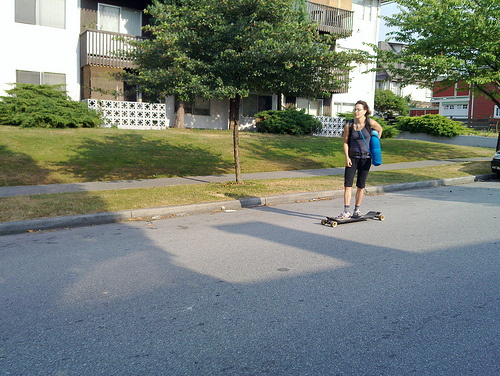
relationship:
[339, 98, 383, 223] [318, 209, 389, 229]
woman on a black skateboard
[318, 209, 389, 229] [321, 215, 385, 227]
skateboard has brown wheels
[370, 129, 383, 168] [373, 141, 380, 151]
bag for yoga blue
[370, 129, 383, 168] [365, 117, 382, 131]
bag for yoga on shoulder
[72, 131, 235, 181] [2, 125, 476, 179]
shadow on grass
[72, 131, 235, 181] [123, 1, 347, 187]
shadow of a tree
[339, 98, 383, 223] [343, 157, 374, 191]
woman wearing black pants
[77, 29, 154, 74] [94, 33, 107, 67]
railing brown with vertical slats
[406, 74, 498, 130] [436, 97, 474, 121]
building red with white garage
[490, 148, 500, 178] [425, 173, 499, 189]
car parked at curb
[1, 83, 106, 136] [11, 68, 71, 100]
bush in front of a window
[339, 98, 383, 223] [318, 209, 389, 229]
woman on a skateboard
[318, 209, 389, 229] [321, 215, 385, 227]
skateboard has white wheels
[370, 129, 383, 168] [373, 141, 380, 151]
bag on woman blue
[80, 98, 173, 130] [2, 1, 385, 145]
white fence in front of building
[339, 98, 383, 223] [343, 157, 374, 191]
woman in black capri pants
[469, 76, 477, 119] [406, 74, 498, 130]
white trim on building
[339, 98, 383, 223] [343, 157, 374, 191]
woman wearing shorts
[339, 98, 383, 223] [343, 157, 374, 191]
woman wearing black shorts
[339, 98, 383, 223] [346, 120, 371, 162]
woman wearing a shirt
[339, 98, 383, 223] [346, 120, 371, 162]
woman wearing a gray shirt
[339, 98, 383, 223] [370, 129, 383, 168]
woman carrying a yoga mat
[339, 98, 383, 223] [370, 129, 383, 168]
woman holding yoga mat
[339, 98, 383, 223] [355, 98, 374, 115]
person has brown hair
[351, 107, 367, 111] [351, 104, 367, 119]
glasses on persons face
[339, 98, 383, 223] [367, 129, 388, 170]
person carrying a blue yoga mat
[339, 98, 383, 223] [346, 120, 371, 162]
person wearing a gray shirt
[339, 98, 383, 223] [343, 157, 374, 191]
person wearing black shorts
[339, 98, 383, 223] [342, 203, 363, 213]
person wearing gray socks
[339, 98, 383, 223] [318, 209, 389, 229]
person standing on skateboard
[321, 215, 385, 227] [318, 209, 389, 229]
wheels are tan on skateboard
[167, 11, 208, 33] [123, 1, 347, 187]
leaves are green on tree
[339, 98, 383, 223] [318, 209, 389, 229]
woman riding a skateboard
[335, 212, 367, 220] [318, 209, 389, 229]
feet are on skateboard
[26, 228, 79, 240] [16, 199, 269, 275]
leaves on side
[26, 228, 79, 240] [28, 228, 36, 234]
leaves on side are dry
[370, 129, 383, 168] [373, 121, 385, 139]
blue roll tucked under arm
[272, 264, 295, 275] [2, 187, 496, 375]
black spot on road surface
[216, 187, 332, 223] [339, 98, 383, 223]
shadow of skater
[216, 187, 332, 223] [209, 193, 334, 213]
shadow on curb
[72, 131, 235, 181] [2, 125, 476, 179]
shadow cast on grass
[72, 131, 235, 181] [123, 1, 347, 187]
shadow cast by a tree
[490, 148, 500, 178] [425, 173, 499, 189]
car sticking out near curb